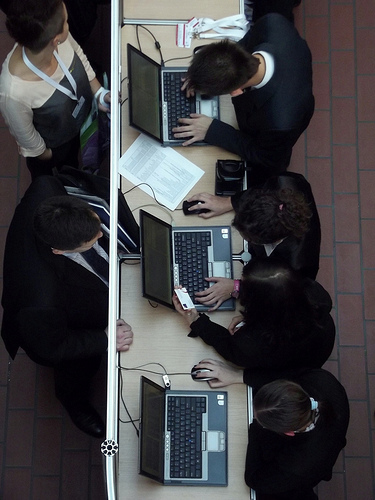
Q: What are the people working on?
A: Computers.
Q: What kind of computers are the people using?
A: Laptops.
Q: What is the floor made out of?
A: Bricks.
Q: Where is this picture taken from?
A: Above.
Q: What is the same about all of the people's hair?
A: It is brown.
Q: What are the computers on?
A: Desk.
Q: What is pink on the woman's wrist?
A: Watch.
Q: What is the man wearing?
A: A suit.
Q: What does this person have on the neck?
A: A necklace.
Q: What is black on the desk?
A: The laptop.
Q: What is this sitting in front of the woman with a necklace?
A: This is a man.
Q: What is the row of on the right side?
A: People dressed in black suits.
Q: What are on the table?
A: Laptop.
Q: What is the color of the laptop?
A: Black.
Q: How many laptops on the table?
A: Three.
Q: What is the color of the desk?
A: Brown.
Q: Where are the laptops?
A: On the desk.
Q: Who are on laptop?
A: Women and men.